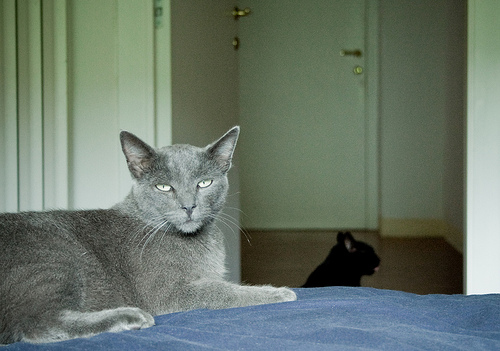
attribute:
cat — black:
[292, 219, 384, 301]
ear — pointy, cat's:
[119, 129, 160, 181]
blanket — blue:
[0, 284, 498, 349]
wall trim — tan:
[383, 219, 454, 237]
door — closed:
[237, 0, 378, 228]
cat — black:
[302, 224, 381, 288]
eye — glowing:
[199, 177, 214, 185]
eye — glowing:
[154, 183, 171, 190]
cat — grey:
[5, 122, 298, 338]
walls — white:
[381, 1, 460, 245]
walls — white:
[172, 0, 234, 132]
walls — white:
[3, 2, 168, 196]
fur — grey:
[25, 252, 160, 300]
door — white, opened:
[154, 3, 241, 268]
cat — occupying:
[302, 231, 384, 296]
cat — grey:
[2, 103, 357, 348]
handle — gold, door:
[311, 46, 403, 88]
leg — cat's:
[182, 270, 298, 310]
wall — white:
[0, 0, 171, 210]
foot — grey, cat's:
[51, 287, 158, 339]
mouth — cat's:
[170, 210, 202, 227]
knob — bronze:
[349, 60, 365, 79]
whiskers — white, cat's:
[206, 211, 238, 238]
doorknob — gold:
[352, 62, 367, 77]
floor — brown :
[248, 220, 467, 293]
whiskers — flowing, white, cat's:
[108, 192, 278, 269]